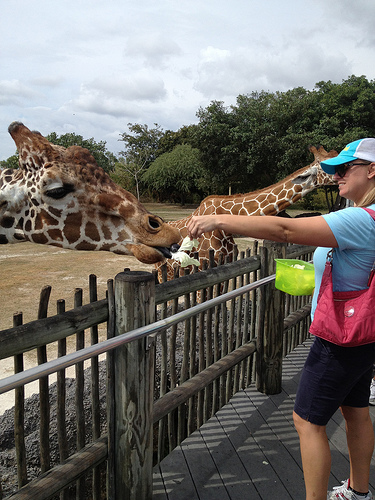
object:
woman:
[185, 136, 374, 499]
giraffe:
[0, 121, 182, 264]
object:
[272, 255, 318, 296]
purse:
[307, 204, 375, 346]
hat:
[319, 136, 374, 175]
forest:
[0, 74, 375, 208]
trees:
[139, 143, 208, 204]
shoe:
[324, 479, 371, 500]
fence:
[0, 240, 328, 500]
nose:
[141, 211, 183, 236]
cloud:
[92, 65, 166, 103]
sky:
[0, 0, 375, 163]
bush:
[142, 145, 212, 205]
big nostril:
[147, 214, 160, 229]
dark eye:
[42, 185, 71, 199]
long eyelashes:
[43, 183, 76, 193]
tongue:
[151, 244, 175, 259]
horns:
[7, 121, 38, 159]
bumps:
[81, 166, 87, 176]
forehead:
[51, 146, 110, 184]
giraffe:
[153, 145, 341, 314]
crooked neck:
[202, 166, 312, 219]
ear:
[0, 185, 24, 216]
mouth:
[135, 229, 182, 264]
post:
[115, 269, 156, 500]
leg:
[291, 335, 353, 499]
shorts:
[292, 330, 374, 426]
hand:
[186, 212, 214, 238]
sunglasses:
[331, 162, 356, 176]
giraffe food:
[294, 263, 310, 270]